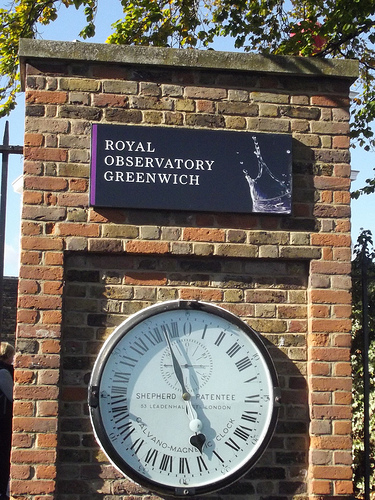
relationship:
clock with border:
[88, 297, 281, 495] [84, 286, 288, 498]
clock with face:
[88, 297, 281, 495] [99, 311, 274, 487]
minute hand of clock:
[160, 325, 190, 400] [88, 297, 281, 495]